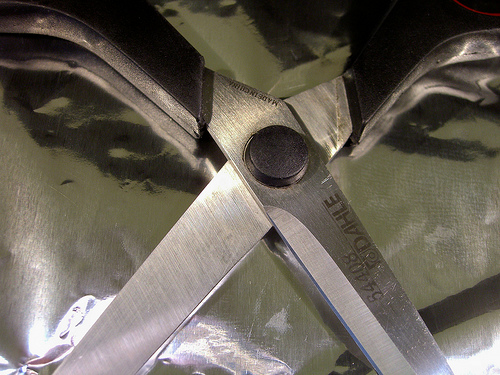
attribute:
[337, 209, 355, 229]
letter — h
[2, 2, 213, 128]
handle — black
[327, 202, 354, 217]
letter — l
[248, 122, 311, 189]
connector — black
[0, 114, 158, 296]
foil — aluminum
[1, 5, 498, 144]
handle — plastic, black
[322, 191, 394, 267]
dahle — printed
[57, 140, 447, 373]
blade — one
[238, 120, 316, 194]
dot — black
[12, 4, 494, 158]
handle — one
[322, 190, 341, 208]
letter — e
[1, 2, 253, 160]
handle — black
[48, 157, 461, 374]
blades — silver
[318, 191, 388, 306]
writing — made in china